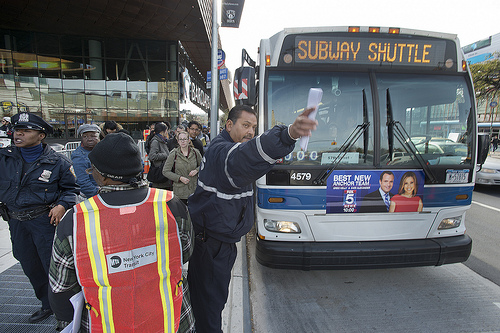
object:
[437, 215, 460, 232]
headlight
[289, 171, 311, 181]
number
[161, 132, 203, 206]
lady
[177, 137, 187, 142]
eyeglasses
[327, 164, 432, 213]
sign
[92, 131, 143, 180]
hat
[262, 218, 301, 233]
headlight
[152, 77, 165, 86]
window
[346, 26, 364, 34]
orange light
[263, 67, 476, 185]
windshield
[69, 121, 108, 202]
lady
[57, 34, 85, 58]
window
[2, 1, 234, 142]
building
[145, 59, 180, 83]
window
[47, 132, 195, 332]
man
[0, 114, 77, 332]
officer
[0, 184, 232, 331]
sidewalk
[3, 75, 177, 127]
window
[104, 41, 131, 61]
window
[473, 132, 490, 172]
mirror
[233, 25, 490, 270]
bus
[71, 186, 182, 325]
vest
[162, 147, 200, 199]
jacket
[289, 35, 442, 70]
screen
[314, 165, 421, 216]
advertisement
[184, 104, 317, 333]
man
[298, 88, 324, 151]
papers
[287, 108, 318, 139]
hand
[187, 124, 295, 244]
jacket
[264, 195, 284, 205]
light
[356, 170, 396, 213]
man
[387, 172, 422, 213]
lady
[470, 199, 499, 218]
line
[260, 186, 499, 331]
street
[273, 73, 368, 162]
window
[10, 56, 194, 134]
window